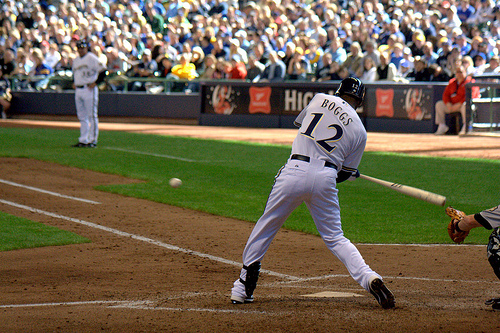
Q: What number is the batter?
A: 12.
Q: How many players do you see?
A: 2.